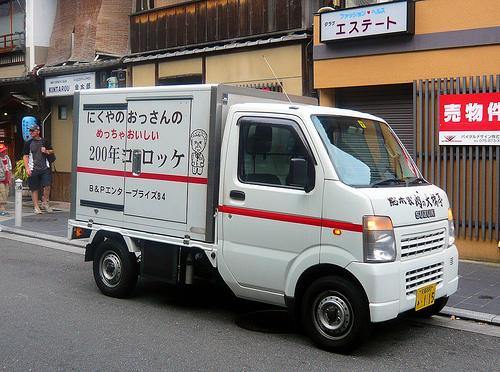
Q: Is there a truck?
A: Yes, there is a truck.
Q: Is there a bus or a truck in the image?
A: Yes, there is a truck.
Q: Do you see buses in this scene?
A: No, there are no buses.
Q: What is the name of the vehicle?
A: The vehicle is a truck.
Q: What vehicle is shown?
A: The vehicle is a truck.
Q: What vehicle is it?
A: The vehicle is a truck.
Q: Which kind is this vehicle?
A: This is a truck.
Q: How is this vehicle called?
A: This is a truck.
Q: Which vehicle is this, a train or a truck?
A: This is a truck.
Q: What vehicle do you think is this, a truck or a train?
A: This is a truck.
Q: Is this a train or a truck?
A: This is a truck.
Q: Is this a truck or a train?
A: This is a truck.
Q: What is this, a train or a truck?
A: This is a truck.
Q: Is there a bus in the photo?
A: No, there are no buses.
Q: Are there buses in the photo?
A: No, there are no buses.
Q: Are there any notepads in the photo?
A: No, there are no notepads.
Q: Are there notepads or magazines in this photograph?
A: No, there are no notepads or magazines.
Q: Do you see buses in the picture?
A: No, there are no buses.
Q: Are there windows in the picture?
A: Yes, there is a window.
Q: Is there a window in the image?
A: Yes, there is a window.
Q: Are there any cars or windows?
A: Yes, there is a window.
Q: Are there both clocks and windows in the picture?
A: No, there is a window but no clocks.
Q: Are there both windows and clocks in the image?
A: No, there is a window but no clocks.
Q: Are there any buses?
A: No, there are no buses.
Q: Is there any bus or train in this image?
A: No, there are no buses or trains.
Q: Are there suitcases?
A: No, there are no suitcases.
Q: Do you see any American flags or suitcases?
A: No, there are no suitcases or American flags.